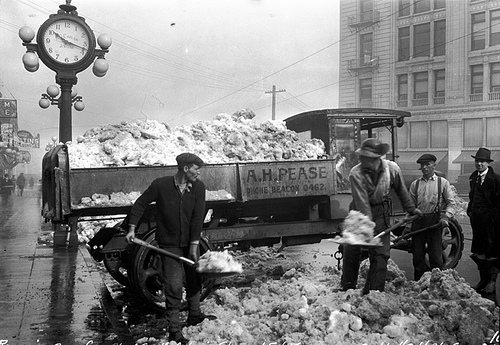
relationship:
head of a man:
[167, 157, 207, 197] [124, 152, 217, 344]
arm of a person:
[130, 198, 140, 236] [106, 141, 214, 321]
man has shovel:
[99, 144, 257, 340] [117, 222, 252, 288]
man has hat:
[338, 135, 433, 310] [349, 136, 394, 166]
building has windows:
[336, 1, 499, 228] [350, 5, 493, 146]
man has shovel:
[330, 137, 422, 297] [335, 197, 435, 251]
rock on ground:
[381, 323, 403, 338] [44, 266, 476, 337]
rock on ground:
[324, 305, 351, 335] [6, 154, 495, 341]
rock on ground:
[381, 323, 403, 338] [6, 154, 495, 341]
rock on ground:
[381, 323, 403, 338] [4, 125, 489, 341]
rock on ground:
[270, 304, 297, 324] [6, 154, 495, 341]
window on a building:
[412, 22, 428, 57] [330, 2, 499, 211]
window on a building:
[412, 22, 428, 57] [336, 1, 499, 228]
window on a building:
[412, 22, 428, 57] [341, 0, 499, 181]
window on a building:
[412, 22, 428, 57] [341, 11, 499, 189]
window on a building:
[408, 18, 429, 59] [336, 1, 499, 228]